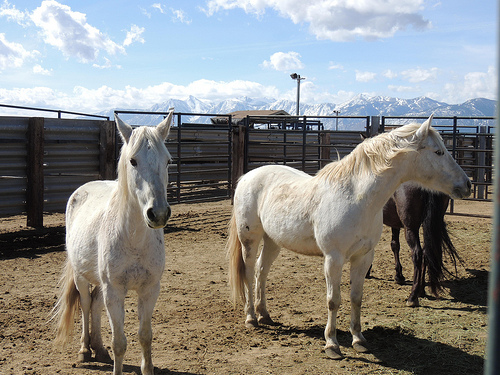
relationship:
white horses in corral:
[83, 115, 461, 345] [27, 117, 325, 338]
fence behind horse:
[3, 102, 498, 242] [221, 106, 469, 334]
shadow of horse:
[265, 317, 485, 373] [232, 115, 475, 347]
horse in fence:
[54, 102, 216, 373] [0, 103, 500, 228]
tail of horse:
[218, 200, 255, 308] [205, 106, 473, 354]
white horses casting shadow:
[225, 114, 473, 358] [265, 317, 485, 373]